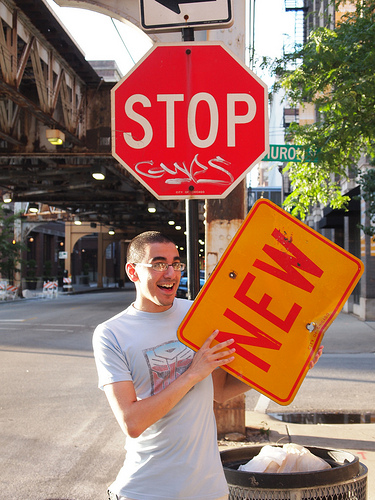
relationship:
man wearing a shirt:
[92, 231, 324, 498] [93, 297, 231, 499]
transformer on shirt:
[143, 340, 196, 417] [93, 297, 231, 499]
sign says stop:
[110, 41, 270, 201] [123, 94, 256, 149]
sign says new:
[177, 198, 365, 407] [212, 228, 324, 372]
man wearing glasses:
[92, 231, 324, 498] [127, 263, 185, 273]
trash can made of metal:
[220, 446, 369, 499] [219, 444, 368, 499]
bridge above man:
[0, 0, 203, 299] [92, 231, 324, 498]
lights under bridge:
[1, 130, 203, 257] [0, 0, 203, 299]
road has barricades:
[0, 282, 374, 498] [0, 276, 73, 302]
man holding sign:
[92, 231, 324, 498] [177, 198, 365, 407]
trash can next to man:
[220, 446, 369, 499] [92, 231, 324, 498]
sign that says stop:
[110, 41, 270, 201] [123, 94, 256, 149]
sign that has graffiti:
[110, 41, 270, 201] [135, 154, 234, 186]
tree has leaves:
[245, 0, 374, 242] [247, 0, 374, 244]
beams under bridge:
[0, 0, 205, 260] [0, 0, 203, 299]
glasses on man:
[127, 263, 185, 273] [92, 231, 324, 498]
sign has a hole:
[177, 198, 365, 407] [228, 272, 236, 280]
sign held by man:
[177, 198, 365, 407] [92, 231, 324, 498]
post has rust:
[206, 0, 246, 443] [206, 174, 246, 442]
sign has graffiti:
[110, 41, 270, 201] [135, 154, 234, 186]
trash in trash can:
[236, 443, 332, 470] [220, 446, 369, 499]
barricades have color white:
[0, 276, 73, 302] [0, 276, 74, 302]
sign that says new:
[177, 198, 365, 407] [212, 228, 324, 372]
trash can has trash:
[220, 446, 369, 499] [236, 443, 332, 470]